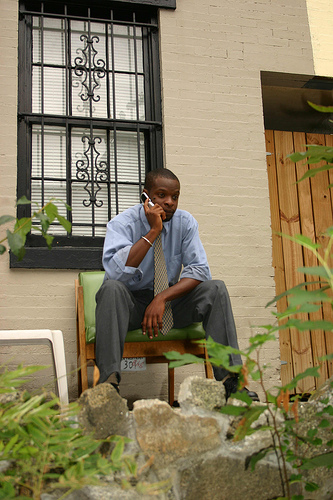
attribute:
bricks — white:
[195, 93, 238, 221]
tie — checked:
[156, 251, 174, 316]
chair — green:
[74, 265, 101, 383]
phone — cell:
[132, 184, 159, 220]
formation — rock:
[82, 385, 297, 493]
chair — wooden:
[66, 294, 89, 372]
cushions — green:
[136, 326, 143, 339]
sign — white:
[123, 359, 144, 372]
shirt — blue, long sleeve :
[108, 205, 209, 285]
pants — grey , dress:
[102, 276, 237, 375]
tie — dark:
[144, 230, 188, 331]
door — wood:
[248, 73, 329, 333]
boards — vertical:
[270, 128, 320, 244]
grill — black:
[28, 26, 150, 240]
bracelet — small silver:
[134, 226, 170, 259]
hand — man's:
[130, 193, 173, 247]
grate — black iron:
[22, 16, 165, 221]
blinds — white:
[42, 43, 121, 112]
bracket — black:
[275, 380, 317, 406]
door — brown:
[245, 111, 323, 427]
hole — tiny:
[313, 186, 330, 204]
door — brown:
[249, 80, 325, 373]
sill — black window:
[4, 218, 93, 282]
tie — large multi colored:
[146, 233, 180, 298]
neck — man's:
[131, 189, 177, 231]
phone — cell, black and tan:
[138, 186, 162, 218]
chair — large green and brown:
[69, 263, 217, 369]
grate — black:
[28, 22, 167, 235]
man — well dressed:
[84, 166, 218, 363]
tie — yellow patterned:
[137, 222, 195, 329]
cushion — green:
[83, 260, 142, 333]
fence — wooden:
[262, 108, 324, 285]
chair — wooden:
[81, 262, 206, 375]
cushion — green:
[95, 323, 187, 358]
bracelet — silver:
[138, 232, 156, 246]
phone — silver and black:
[134, 169, 159, 218]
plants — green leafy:
[7, 371, 88, 484]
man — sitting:
[75, 162, 220, 355]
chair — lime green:
[76, 264, 214, 376]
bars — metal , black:
[53, 72, 128, 162]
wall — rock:
[192, 108, 250, 209]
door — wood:
[254, 128, 332, 302]